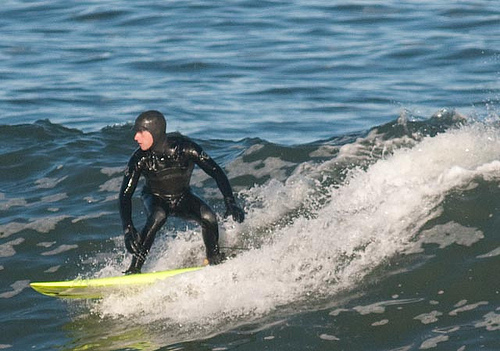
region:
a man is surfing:
[23, 92, 310, 307]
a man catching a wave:
[18, 80, 343, 316]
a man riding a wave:
[9, 90, 273, 327]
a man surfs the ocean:
[9, 6, 484, 335]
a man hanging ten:
[17, 39, 372, 325]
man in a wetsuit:
[95, 97, 257, 291]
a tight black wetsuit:
[96, 90, 253, 295]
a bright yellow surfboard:
[15, 248, 280, 313]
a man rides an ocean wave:
[16, 69, 406, 349]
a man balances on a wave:
[13, 70, 480, 337]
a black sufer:
[27, 100, 267, 346]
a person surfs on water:
[20, 102, 275, 314]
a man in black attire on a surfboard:
[17, 97, 296, 346]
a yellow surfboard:
[22, 254, 283, 322]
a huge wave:
[4, 101, 475, 323]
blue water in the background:
[2, 49, 497, 228]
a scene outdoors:
[10, 62, 443, 344]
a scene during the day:
[13, 56, 498, 348]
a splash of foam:
[200, 111, 474, 321]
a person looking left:
[93, 113, 262, 288]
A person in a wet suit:
[99, 90, 234, 287]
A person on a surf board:
[49, 98, 259, 308]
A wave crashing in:
[256, 83, 451, 248]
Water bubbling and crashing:
[281, 118, 455, 280]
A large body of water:
[151, 36, 348, 120]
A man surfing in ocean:
[24, 77, 417, 302]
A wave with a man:
[56, 93, 486, 166]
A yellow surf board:
[21, 254, 216, 298]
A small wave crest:
[6, 98, 70, 151]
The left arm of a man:
[193, 139, 268, 231]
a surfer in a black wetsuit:
[101, 98, 259, 283]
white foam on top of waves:
[270, 155, 440, 280]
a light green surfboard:
[20, 265, 220, 305]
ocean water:
[175, 20, 360, 100]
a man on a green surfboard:
[30, 105, 295, 325]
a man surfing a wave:
[20, 90, 295, 300]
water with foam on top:
[385, 285, 490, 345]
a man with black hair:
[118, 106, 178, 161]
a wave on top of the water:
[240, 118, 497, 303]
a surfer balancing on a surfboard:
[19, 90, 278, 311]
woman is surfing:
[44, 103, 284, 298]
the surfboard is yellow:
[26, 261, 248, 306]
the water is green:
[99, 19, 338, 141]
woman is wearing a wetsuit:
[88, 121, 306, 286]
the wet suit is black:
[72, 141, 257, 273]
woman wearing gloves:
[80, 200, 275, 279]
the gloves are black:
[104, 196, 285, 282]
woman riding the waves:
[1, 83, 341, 349]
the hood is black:
[114, 93, 208, 184]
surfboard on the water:
[11, 244, 261, 299]